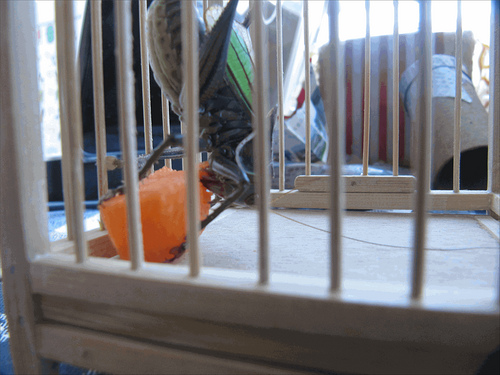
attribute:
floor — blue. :
[0, 204, 113, 369]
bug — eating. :
[93, 0, 343, 259]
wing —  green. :
[195, 4, 287, 135]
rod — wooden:
[237, 46, 283, 238]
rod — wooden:
[308, 27, 365, 242]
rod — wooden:
[413, 25, 455, 231]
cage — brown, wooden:
[48, 7, 472, 298]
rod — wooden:
[361, 0, 372, 179]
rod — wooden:
[244, 1, 296, 292]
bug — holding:
[102, 0, 268, 273]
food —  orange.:
[101, 164, 196, 254]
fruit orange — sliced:
[108, 170, 223, 256]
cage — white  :
[315, 59, 480, 303]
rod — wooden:
[270, 1, 287, 188]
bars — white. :
[42, 31, 470, 283]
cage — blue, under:
[20, 23, 482, 275]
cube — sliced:
[97, 162, 212, 262]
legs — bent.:
[201, 2, 240, 119]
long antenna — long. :
[343, 233, 411, 253]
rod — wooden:
[412, 0, 432, 302]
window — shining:
[329, 0, 498, 35]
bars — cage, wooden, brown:
[323, 0, 432, 299]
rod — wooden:
[408, 0, 434, 300]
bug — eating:
[149, 0, 314, 239]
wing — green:
[208, 22, 258, 114]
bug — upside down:
[95, 0, 497, 261]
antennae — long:
[246, 53, 452, 270]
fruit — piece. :
[106, 166, 209, 252]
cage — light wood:
[4, 6, 484, 367]